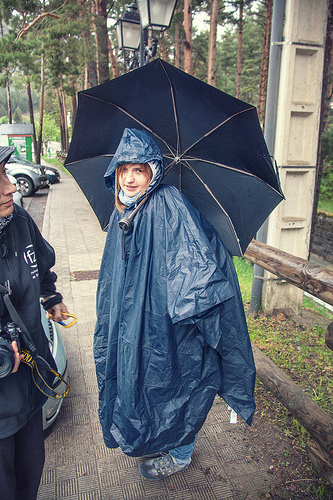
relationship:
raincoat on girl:
[93, 127, 257, 457] [92, 125, 256, 480]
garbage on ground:
[213, 402, 260, 427] [46, 291, 327, 499]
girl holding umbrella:
[99, 125, 242, 481] [53, 57, 309, 265]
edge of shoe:
[161, 473, 167, 478] [137, 454, 194, 480]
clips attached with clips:
[246, 0, 284, 318] [254, 41, 284, 282]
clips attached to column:
[246, 0, 284, 318] [260, 30, 321, 307]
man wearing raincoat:
[0, 147, 77, 499] [93, 127, 257, 457]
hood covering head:
[101, 124, 167, 210] [102, 133, 161, 207]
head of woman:
[102, 133, 161, 207] [100, 126, 214, 482]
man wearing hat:
[0, 147, 77, 499] [0, 139, 20, 158]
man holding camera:
[0, 147, 77, 499] [0, 288, 73, 398]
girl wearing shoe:
[92, 125, 256, 480] [138, 453, 194, 484]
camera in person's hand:
[0, 336, 40, 380] [7, 335, 30, 373]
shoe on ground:
[134, 453, 193, 481] [24, 320, 332, 498]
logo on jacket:
[20, 243, 51, 291] [2, 201, 89, 443]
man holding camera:
[0, 147, 77, 499] [1, 283, 67, 399]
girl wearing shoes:
[92, 125, 256, 480] [138, 456, 190, 479]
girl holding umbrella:
[92, 125, 256, 480] [64, 59, 289, 245]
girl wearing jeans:
[92, 125, 256, 480] [137, 433, 198, 479]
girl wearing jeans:
[92, 125, 256, 480] [169, 433, 198, 459]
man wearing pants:
[0, 147, 54, 492] [0, 409, 53, 495]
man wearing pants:
[0, 147, 77, 499] [0, 407, 44, 498]